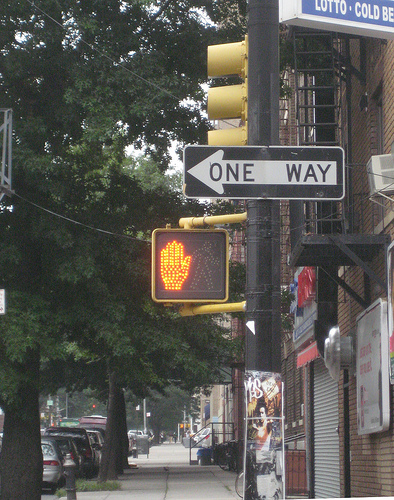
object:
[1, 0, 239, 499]
trees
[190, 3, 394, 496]
buildings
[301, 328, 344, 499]
garage door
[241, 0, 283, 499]
black pole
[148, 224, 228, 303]
traffic lights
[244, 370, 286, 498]
poster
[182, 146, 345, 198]
traffic sign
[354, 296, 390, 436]
sign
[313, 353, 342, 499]
metal gate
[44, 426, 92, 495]
car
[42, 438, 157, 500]
curb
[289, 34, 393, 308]
fire escape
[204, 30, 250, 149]
lights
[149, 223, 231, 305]
signal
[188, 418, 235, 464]
rail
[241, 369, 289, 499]
graffiti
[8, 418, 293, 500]
street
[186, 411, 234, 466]
steps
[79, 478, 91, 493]
grass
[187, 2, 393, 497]
business